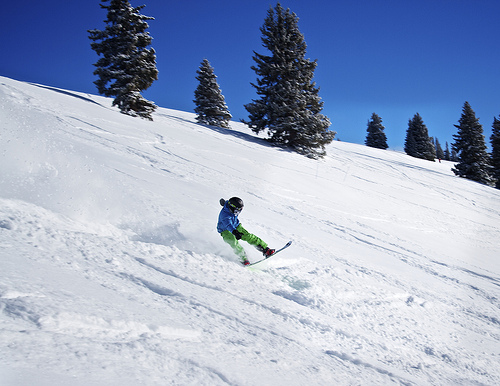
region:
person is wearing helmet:
[212, 184, 249, 232]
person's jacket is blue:
[207, 194, 253, 235]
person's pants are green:
[212, 223, 284, 270]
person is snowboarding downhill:
[182, 164, 296, 296]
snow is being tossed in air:
[2, 96, 154, 255]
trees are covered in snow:
[85, 2, 353, 151]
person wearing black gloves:
[220, 223, 250, 247]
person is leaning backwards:
[201, 179, 311, 285]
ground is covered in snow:
[4, 68, 480, 379]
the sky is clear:
[0, 0, 475, 160]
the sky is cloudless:
[361, 25, 497, 120]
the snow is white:
[113, 275, 274, 373]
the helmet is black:
[212, 198, 247, 210]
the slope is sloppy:
[40, 145, 482, 335]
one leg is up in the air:
[211, 193, 295, 268]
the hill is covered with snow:
[17, 141, 494, 348]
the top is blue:
[212, 206, 247, 233]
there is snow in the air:
[35, 165, 109, 198]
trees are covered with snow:
[103, 12, 315, 137]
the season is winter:
[2, 3, 497, 384]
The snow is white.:
[107, 258, 207, 368]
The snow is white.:
[120, 254, 328, 372]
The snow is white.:
[198, 298, 329, 383]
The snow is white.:
[125, 290, 249, 377]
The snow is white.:
[108, 328, 200, 382]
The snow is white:
[1, 63, 498, 378]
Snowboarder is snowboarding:
[202, 178, 299, 280]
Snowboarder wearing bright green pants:
[207, 180, 298, 276]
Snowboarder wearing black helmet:
[202, 160, 321, 276]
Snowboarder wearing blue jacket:
[209, 185, 297, 274]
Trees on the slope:
[78, 0, 498, 184]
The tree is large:
[241, 2, 340, 159]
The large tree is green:
[237, 0, 332, 167]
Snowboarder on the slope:
[201, 186, 293, 273]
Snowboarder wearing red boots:
[208, 175, 313, 278]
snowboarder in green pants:
[207, 188, 296, 264]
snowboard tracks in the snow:
[130, 265, 305, 358]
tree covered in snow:
[253, 10, 328, 152]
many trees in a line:
[355, 92, 499, 186]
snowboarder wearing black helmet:
[195, 191, 289, 274]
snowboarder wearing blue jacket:
[212, 207, 246, 239]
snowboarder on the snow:
[210, 193, 287, 267]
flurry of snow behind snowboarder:
[32, 137, 153, 247]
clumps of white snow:
[39, 230, 143, 292]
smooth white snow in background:
[162, 117, 278, 184]